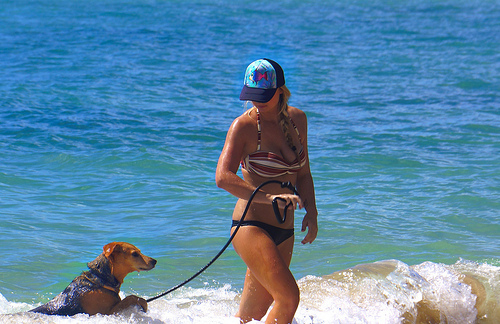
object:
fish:
[244, 66, 274, 86]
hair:
[271, 80, 291, 128]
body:
[4, 4, 494, 323]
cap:
[237, 57, 285, 102]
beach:
[1, 272, 498, 322]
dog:
[32, 231, 159, 322]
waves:
[1, 256, 498, 320]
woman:
[208, 51, 328, 322]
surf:
[2, 248, 498, 323]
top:
[245, 108, 309, 182]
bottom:
[227, 217, 296, 248]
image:
[247, 64, 268, 85]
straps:
[246, 105, 309, 156]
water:
[2, 1, 498, 322]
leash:
[143, 174, 304, 302]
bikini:
[227, 100, 303, 241]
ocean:
[127, 4, 233, 54]